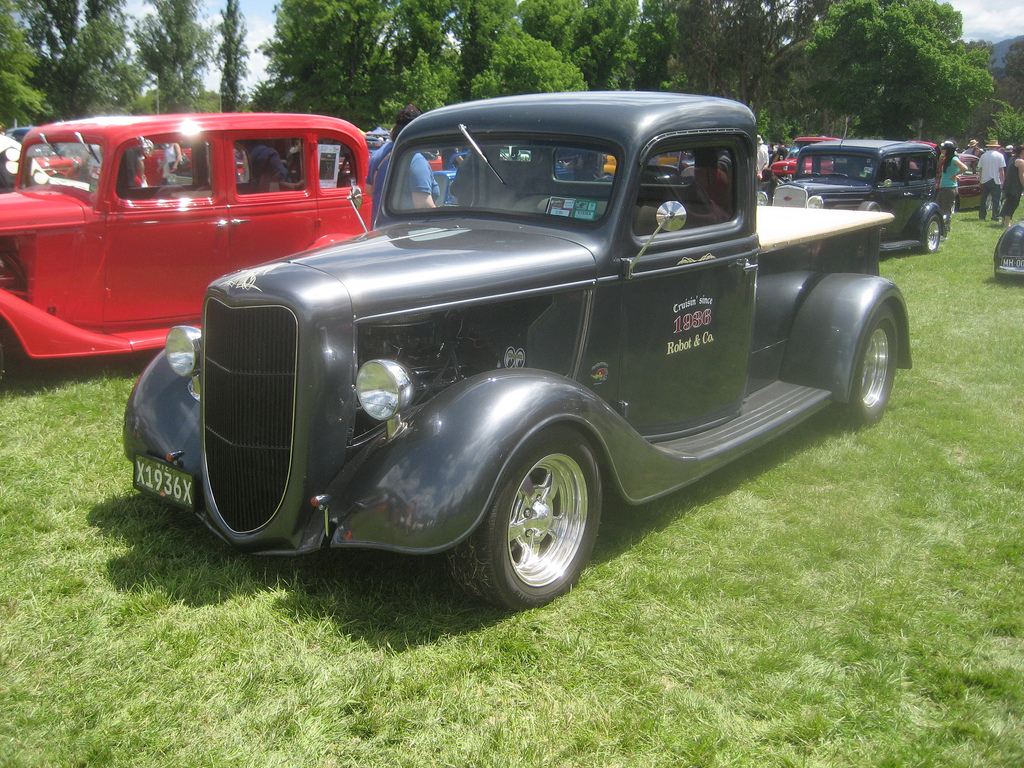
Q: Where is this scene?
A: At a truck show.